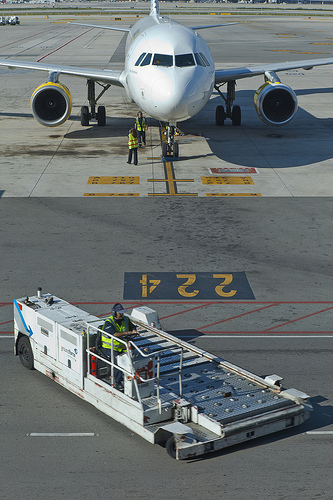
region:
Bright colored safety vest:
[99, 313, 132, 352]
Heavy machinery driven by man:
[13, 286, 314, 460]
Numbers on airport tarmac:
[121, 269, 256, 300]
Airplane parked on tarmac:
[0, 0, 332, 159]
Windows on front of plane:
[132, 51, 210, 68]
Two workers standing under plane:
[127, 110, 146, 164]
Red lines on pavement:
[0, 297, 331, 335]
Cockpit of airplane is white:
[128, 30, 214, 124]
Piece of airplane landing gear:
[215, 79, 242, 126]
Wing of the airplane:
[0, 56, 127, 85]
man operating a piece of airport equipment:
[99, 301, 139, 390]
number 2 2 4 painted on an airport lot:
[123, 271, 256, 299]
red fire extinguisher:
[89, 346, 96, 375]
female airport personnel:
[126, 126, 137, 165]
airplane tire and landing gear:
[80, 79, 105, 127]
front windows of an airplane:
[134, 50, 209, 70]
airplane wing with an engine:
[0, 58, 121, 127]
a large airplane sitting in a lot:
[0, 2, 330, 161]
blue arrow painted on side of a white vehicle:
[13, 300, 32, 339]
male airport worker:
[133, 111, 148, 147]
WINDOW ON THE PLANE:
[155, 55, 172, 67]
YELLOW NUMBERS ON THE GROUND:
[125, 274, 256, 297]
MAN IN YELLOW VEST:
[121, 323, 130, 329]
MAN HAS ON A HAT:
[119, 306, 124, 311]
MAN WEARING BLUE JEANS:
[105, 350, 108, 353]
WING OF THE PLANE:
[232, 60, 306, 66]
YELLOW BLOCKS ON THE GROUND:
[207, 190, 260, 199]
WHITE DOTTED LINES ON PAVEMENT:
[24, 430, 107, 438]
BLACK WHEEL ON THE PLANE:
[234, 103, 245, 122]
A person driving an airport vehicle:
[102, 305, 139, 385]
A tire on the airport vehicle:
[17, 339, 33, 367]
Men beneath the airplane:
[129, 111, 145, 164]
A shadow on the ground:
[188, 395, 330, 464]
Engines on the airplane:
[31, 80, 299, 124]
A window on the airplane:
[135, 52, 206, 66]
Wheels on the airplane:
[215, 105, 241, 124]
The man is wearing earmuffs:
[112, 303, 123, 317]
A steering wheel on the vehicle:
[119, 331, 138, 341]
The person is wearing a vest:
[126, 132, 138, 149]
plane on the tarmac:
[0, 0, 332, 160]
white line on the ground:
[23, 424, 107, 443]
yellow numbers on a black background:
[119, 267, 255, 301]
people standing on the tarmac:
[118, 105, 153, 163]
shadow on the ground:
[179, 383, 332, 467]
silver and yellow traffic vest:
[96, 315, 138, 354]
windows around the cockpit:
[130, 45, 212, 76]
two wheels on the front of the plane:
[157, 137, 180, 160]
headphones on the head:
[110, 299, 126, 319]